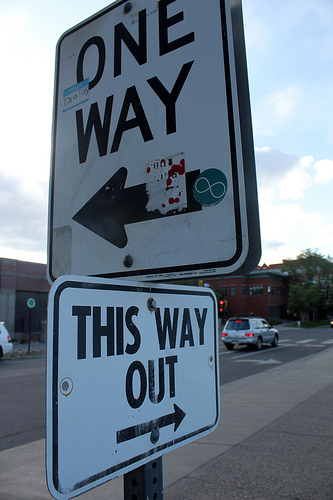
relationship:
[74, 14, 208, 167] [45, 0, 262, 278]
letters on sign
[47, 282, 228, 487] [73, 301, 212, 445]
sign means exit here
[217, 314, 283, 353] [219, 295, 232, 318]
car at light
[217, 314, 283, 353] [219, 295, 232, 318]
car stopped at light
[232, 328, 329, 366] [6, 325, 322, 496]
markings in street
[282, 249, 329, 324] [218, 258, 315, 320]
trees near buidling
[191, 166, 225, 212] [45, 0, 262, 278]
sticker on sign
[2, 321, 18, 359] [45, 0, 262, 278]
van behind sign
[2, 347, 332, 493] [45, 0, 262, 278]
sidewalk behind sign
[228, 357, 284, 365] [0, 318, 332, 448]
arrow on road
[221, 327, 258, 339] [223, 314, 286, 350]
taillights on van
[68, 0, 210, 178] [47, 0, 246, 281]
lettering on street sign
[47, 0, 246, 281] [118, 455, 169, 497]
street sign on pole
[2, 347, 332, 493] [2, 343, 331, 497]
sidewalk has surface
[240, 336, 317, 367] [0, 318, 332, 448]
lines painted on road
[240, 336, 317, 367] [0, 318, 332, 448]
lines on road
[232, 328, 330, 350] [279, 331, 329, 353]
crosswalk has stripes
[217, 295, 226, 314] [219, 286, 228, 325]
stoplight on post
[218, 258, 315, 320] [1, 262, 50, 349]
buidling has wall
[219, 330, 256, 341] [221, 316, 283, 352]
break lights on truck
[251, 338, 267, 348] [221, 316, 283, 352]
wheel on truck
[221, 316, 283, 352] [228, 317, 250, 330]
truck has rear window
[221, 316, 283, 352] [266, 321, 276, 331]
truck has side mirror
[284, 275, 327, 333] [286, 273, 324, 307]
tree has leaves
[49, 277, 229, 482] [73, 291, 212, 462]
sign post showing "this way out"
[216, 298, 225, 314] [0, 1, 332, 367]
lights in background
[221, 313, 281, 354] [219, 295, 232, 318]
station wagon stopped at light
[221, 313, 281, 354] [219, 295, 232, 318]
station wagon at light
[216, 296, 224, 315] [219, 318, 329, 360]
traffic light at intersection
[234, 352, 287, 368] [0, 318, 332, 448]
arrow on road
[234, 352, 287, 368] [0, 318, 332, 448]
arrow painted on road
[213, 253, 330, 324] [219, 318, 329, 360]
building across intersection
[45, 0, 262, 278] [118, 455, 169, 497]
sign on pole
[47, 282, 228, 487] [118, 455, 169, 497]
sign on pole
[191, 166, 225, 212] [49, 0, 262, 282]
sticker on top sign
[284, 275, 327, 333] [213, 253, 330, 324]
tree beside building